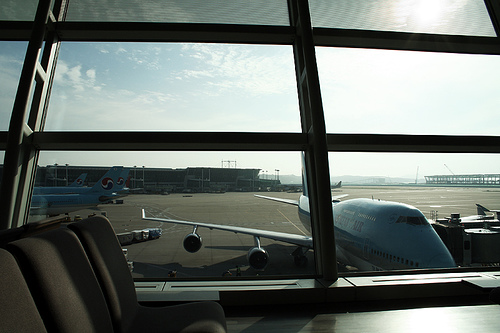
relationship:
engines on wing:
[244, 243, 270, 273] [138, 206, 350, 269]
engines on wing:
[178, 219, 209, 254] [138, 206, 350, 269]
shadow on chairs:
[89, 224, 225, 330] [64, 206, 226, 332]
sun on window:
[403, 2, 473, 33] [309, 0, 499, 48]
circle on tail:
[99, 175, 116, 191] [89, 163, 127, 198]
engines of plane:
[244, 243, 270, 273] [137, 143, 496, 273]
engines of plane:
[178, 219, 209, 254] [137, 143, 496, 273]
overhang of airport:
[422, 208, 498, 256] [1, 1, 499, 330]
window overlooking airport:
[309, 0, 499, 48] [1, 1, 499, 330]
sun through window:
[403, 2, 473, 33] [309, 0, 499, 48]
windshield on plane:
[397, 212, 431, 225] [137, 143, 496, 273]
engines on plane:
[244, 243, 270, 273] [137, 143, 496, 273]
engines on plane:
[178, 219, 209, 254] [137, 143, 496, 273]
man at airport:
[234, 262, 245, 277] [1, 1, 499, 330]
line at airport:
[275, 210, 316, 252] [1, 1, 499, 330]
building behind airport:
[1, 159, 284, 199] [1, 1, 499, 330]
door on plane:
[358, 233, 375, 261] [137, 143, 496, 273]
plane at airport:
[137, 143, 496, 273] [1, 1, 499, 330]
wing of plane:
[138, 206, 350, 269] [137, 143, 496, 273]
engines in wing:
[244, 243, 270, 273] [138, 206, 350, 269]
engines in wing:
[178, 219, 209, 254] [138, 206, 350, 269]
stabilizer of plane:
[288, 244, 312, 268] [137, 143, 496, 273]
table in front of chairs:
[131, 266, 500, 308] [64, 206, 226, 332]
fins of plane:
[253, 191, 305, 212] [137, 143, 496, 273]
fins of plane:
[331, 190, 350, 202] [137, 143, 496, 273]